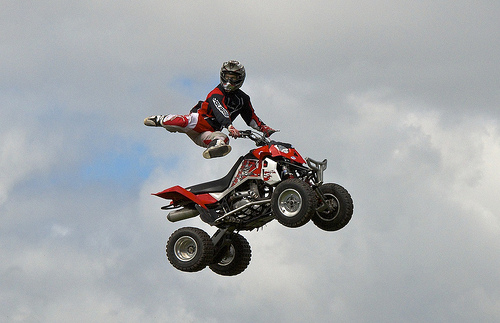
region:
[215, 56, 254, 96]
a man wearing a motorcycle helmet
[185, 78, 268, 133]
a man wearing a motorcycle jacket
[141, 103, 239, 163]
a man wearing a motorcycle pants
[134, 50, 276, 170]
a man with his feet off his 4 wheeler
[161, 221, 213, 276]
The right rear wheel of a 4 wheel bike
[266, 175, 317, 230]
The right front wheel of a 4 wheel bike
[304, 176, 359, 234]
The right front wheel of a 4 wheel bike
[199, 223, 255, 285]
The left rear wheel of a 4 wheel bike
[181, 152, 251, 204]
The black seat of a 4 wheel bike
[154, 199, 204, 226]
The exhaust pipe of a 4 wheel bike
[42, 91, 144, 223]
the blue sky behind clouds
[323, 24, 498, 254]
clouds in the sky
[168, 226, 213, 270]
the tire of the four wheeler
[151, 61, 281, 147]
a man in a helmet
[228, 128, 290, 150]
the handlebars of the four wheeler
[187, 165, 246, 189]
the seat of the four wheeler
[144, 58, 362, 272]
a man jumping off a four wheeler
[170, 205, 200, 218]
the exhaust of the four wheeler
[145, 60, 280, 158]
the man in mid air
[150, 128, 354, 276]
the ATV in mid air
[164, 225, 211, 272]
the wheel on the ATV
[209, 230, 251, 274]
the wheel on the ATV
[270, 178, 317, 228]
the wheel on the ATV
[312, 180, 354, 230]
the wheel on the ATV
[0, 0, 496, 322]
the clouds in the sky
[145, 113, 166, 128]
the shoe on the man's foot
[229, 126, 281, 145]
the handlebar on the ATV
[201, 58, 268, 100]
the head of a man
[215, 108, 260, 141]
the hand of a man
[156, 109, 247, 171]
the legs of a man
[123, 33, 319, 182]
a man in the air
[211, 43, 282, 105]
a man wearing a helmet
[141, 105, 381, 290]
the wheels on a atv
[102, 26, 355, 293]
person holding on to 4 wheeler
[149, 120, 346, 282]
red and white 4 wheeler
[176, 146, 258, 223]
black seat on 4 wheeler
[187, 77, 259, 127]
man wearing black top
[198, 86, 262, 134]
red trim on shirt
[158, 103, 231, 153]
red trim on pants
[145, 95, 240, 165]
man has legs extended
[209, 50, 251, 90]
man wearing grey helmet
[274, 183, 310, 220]
grey rims on tire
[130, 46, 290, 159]
rider doing trick on four wheeler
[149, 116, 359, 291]
four wheeler in air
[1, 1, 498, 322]
sky is mostly cloudy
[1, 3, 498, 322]
sky is mostly gray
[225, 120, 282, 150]
man holding the handlebars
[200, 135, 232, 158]
man wearing boot on left foot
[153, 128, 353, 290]
4 wheeler in the air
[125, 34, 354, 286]
man holding on to handles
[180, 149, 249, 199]
black seat of 4 wheeler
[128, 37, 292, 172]
the man is kicking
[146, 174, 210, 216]
red back of bike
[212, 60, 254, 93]
man wearing a helmet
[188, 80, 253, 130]
a red and black top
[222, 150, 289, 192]
white trim on bike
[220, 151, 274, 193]
red decal on bike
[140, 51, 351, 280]
man is doing a trick